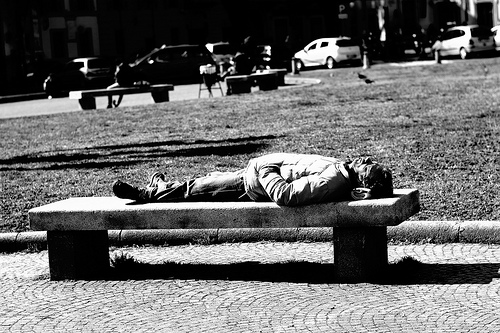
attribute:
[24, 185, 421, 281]
park bench — gray, stone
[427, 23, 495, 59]
car — parked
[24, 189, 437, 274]
bench — cement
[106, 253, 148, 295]
weed — growing, under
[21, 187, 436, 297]
bench — stoned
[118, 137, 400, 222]
person — reclining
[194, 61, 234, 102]
bin — garbage disposal bin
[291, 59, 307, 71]
car tire — round, black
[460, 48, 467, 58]
tire — round, black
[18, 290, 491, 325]
pavement — bricked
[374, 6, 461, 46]
home — background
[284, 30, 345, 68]
car — parked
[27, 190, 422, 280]
bench — stoned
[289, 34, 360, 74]
car — white, background, parked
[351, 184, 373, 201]
cloth — rolled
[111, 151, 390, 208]
man — laying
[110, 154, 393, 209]
person — reclining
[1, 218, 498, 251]
curve — cement